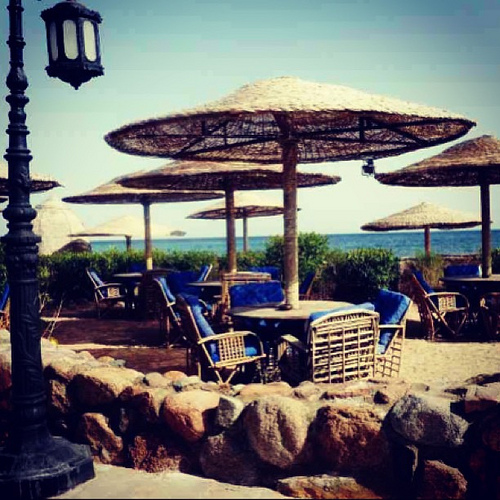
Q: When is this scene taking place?
A: Day time.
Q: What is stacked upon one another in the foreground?
A: Stones.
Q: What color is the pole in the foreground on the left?
A: Black.